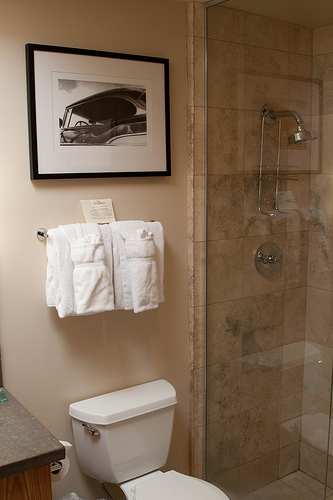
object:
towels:
[45, 221, 164, 320]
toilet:
[69, 377, 228, 500]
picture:
[25, 40, 171, 182]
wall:
[1, 1, 187, 500]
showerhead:
[287, 130, 312, 145]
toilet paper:
[48, 440, 73, 484]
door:
[205, 2, 332, 499]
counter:
[0, 381, 66, 477]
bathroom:
[0, 0, 332, 500]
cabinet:
[0, 464, 53, 499]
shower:
[191, 1, 332, 499]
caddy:
[257, 105, 292, 216]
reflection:
[238, 338, 332, 480]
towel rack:
[37, 225, 53, 241]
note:
[80, 199, 117, 224]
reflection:
[228, 67, 326, 181]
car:
[57, 87, 149, 145]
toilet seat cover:
[118, 467, 231, 499]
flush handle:
[81, 423, 101, 438]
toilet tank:
[67, 379, 177, 484]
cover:
[67, 375, 183, 428]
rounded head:
[293, 130, 312, 143]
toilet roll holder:
[59, 441, 71, 456]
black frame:
[24, 43, 36, 181]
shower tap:
[254, 241, 282, 280]